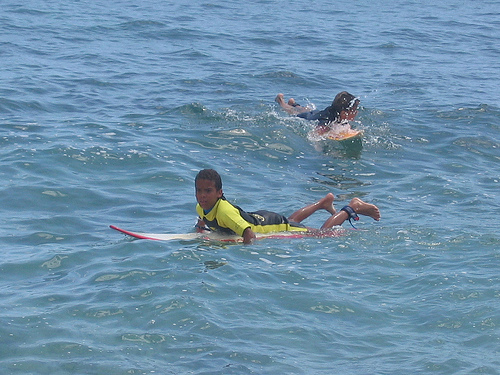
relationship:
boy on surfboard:
[181, 159, 411, 247] [103, 214, 315, 252]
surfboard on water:
[107, 223, 357, 245] [3, 4, 475, 372]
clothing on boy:
[284, 105, 338, 127] [270, 87, 362, 139]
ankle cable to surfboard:
[336, 206, 366, 232] [104, 224, 354, 242]